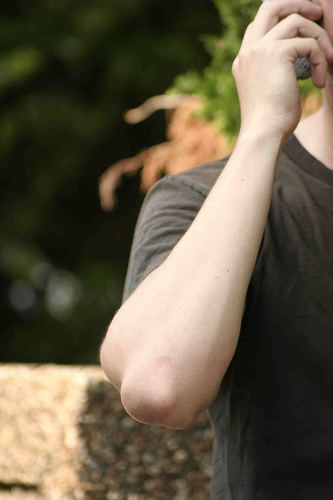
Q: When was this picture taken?
A: Daytime.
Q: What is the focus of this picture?
A: The man's elbow.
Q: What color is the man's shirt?
A: Black.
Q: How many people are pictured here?
A: One.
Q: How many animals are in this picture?
A: Zero.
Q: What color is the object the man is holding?
A: White.